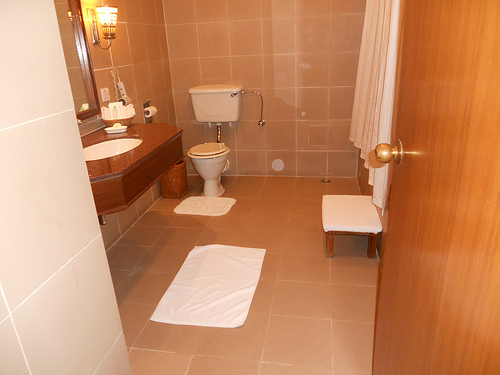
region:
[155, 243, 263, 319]
white towel on ground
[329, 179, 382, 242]
white towel on stool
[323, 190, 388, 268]
wooden small stool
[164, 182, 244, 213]
small white toilet rug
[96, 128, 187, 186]
brown colored hanging sink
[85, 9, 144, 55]
silver fixture hanging from wall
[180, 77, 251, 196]
white ceramic toilet and bowl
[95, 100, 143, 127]
a basket full of towels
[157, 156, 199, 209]
wicker trash can basket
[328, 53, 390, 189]
white shower curtain near stool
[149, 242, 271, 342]
White rug in front of sink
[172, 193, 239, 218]
White rug in front of toilet.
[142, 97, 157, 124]
Roll of toilet paper and holder.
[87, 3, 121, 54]
Light sconce on wall.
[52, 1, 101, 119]
Bathroom mirror on wall.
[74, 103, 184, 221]
Bathroom sink and counter.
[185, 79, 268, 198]
White toilet in bathroom.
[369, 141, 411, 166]
Brass doorknob on bathroom door.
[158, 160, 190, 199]
Small brown garbage bin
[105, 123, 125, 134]
Small white soap dish with soap.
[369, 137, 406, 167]
The door knob is gold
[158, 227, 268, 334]
White towel on the floor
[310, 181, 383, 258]
Stool with a white cover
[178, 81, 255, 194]
The toilet is white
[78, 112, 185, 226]
The counter is brown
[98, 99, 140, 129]
Basket on the counter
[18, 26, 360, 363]
Walls and floor are tiled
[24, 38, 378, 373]
The tiles are tan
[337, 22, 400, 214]
The curtain is white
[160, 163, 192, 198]
The trash bin is brown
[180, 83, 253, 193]
a toilet on a bathroom wall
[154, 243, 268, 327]
a small white rug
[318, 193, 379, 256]
white rug on a wooden stool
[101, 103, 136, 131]
a basket of white towels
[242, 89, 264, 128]
a metal hose on a toilet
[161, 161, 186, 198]
a light brown basket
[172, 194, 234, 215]
a white bath mat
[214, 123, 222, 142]
metal pipe behind a toilet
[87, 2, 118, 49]
a light in a bathroom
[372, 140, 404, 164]
a gold door knob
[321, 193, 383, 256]
Small stool in a bathroom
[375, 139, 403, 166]
Doorknob on bathroom door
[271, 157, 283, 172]
Cover for utility box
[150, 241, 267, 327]
Bath towel lying on the floor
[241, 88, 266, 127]
Plumbing for the toilet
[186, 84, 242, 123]
Water reservoir on the toilet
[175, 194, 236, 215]
Throw rug in front of the toilet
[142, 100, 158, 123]
Toilet paper dispenser on the wall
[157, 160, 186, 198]
Trashcan on bathroom floor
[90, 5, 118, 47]
Light mounted to bathroom wall